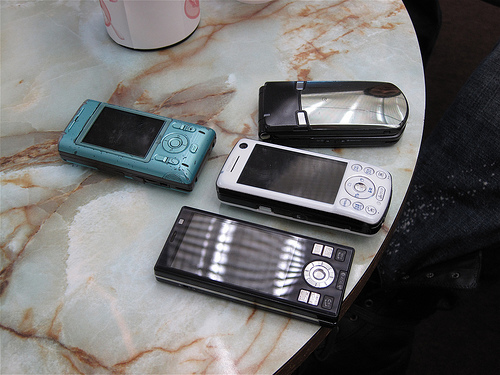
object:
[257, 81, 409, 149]
cell phone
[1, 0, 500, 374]
table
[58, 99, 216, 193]
camera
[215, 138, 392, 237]
cell phone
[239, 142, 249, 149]
camera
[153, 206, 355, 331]
cell phone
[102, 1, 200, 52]
cup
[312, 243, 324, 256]
button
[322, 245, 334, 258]
button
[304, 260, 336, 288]
button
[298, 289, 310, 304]
button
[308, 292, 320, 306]
button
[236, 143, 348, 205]
screen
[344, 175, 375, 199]
control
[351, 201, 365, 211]
button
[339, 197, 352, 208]
button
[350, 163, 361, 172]
button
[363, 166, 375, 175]
button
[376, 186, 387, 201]
button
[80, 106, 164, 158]
screen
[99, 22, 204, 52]
cup bottom